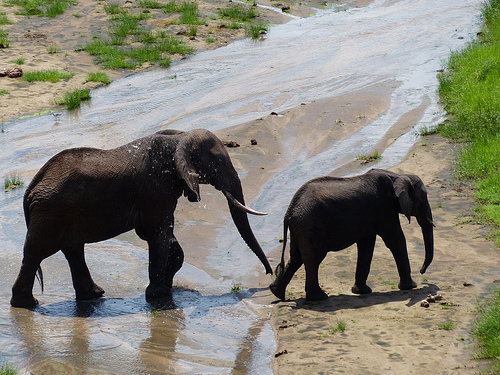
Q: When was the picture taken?
A: Daytime.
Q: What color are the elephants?
A: Gray.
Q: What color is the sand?
A: Brown.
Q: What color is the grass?
A: Green.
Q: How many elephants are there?
A: Two.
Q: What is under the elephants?
A: Sand and water.